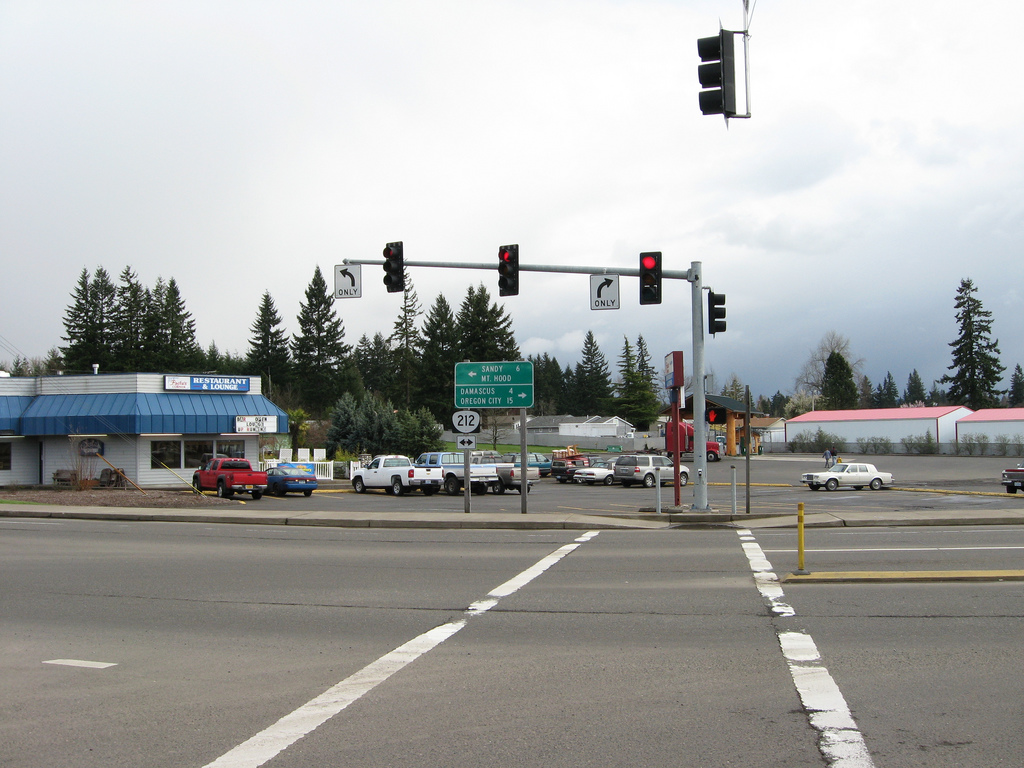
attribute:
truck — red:
[191, 450, 277, 498]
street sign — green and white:
[446, 354, 542, 519]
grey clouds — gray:
[4, 4, 1022, 416]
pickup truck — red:
[184, 449, 274, 504]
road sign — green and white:
[444, 355, 540, 413]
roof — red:
[773, 403, 955, 422]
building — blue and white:
[2, 367, 296, 489]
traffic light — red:
[634, 248, 663, 303]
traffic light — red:
[498, 241, 529, 294]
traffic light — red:
[384, 243, 408, 293]